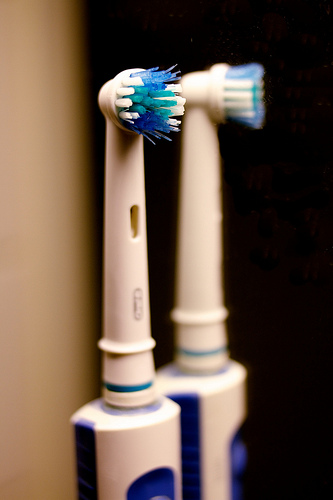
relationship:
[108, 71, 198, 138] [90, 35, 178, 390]
bristles on brush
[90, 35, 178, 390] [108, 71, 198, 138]
brush has bristles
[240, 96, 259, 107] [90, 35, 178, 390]
bristle on brush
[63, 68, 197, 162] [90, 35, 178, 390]
head of brush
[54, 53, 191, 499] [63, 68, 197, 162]
toothbrush has head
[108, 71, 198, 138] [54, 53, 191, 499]
bristles of toothbrush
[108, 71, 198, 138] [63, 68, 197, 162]
bristles on head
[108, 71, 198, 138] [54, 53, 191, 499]
bristles on toothbrush